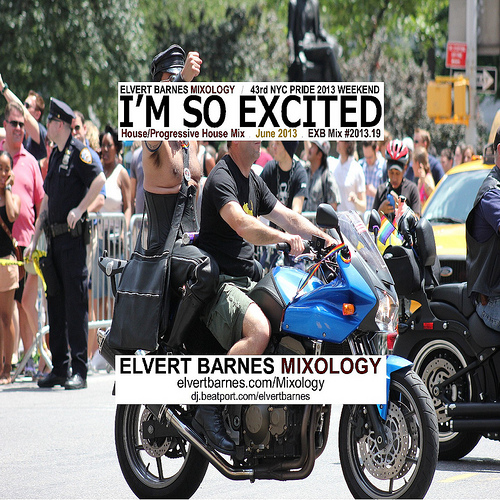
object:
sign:
[112, 352, 386, 406]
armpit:
[147, 142, 166, 166]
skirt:
[0, 255, 19, 292]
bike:
[111, 202, 440, 499]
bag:
[107, 141, 191, 353]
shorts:
[197, 275, 256, 355]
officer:
[22, 96, 105, 392]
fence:
[87, 210, 150, 327]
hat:
[48, 96, 76, 125]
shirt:
[43, 138, 102, 224]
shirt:
[1, 142, 45, 251]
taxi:
[416, 153, 495, 280]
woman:
[94, 126, 132, 327]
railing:
[87, 206, 128, 223]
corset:
[137, 183, 203, 263]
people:
[1, 100, 44, 375]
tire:
[114, 385, 211, 500]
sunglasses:
[47, 114, 60, 124]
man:
[368, 135, 421, 231]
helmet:
[383, 138, 409, 164]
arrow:
[454, 67, 494, 92]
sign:
[444, 40, 469, 71]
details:
[120, 354, 380, 404]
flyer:
[112, 81, 386, 146]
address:
[191, 391, 312, 403]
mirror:
[316, 202, 339, 230]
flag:
[296, 241, 350, 288]